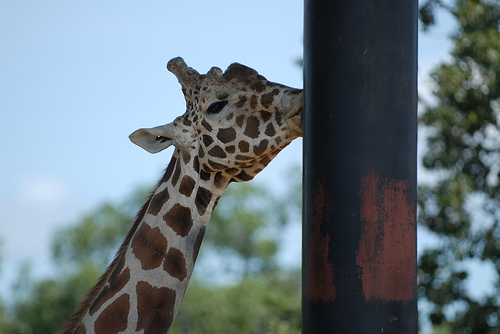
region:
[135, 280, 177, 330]
a brown spot in a giraffe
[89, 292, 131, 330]
a brown spot in a giraffe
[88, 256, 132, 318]
a brown spot in a giraffe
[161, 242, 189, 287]
a brown spot in a giraffe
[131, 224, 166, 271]
a brown spot in a giraffe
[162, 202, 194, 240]
a brown spot in a giraffe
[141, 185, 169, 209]
a brown spot in a giraffe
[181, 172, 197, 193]
a brown spot in a giraffe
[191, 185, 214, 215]
a brown spot in a giraffe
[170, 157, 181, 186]
a brown spot in a giraffe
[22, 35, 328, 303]
a giraffe's head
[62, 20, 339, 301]
a giraffe during the day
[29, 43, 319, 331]
a giraffe licking a pole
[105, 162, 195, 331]
a giraffe's long neck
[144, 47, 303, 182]
a giraffes head during the day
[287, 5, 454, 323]
a tall pole next to the giraffe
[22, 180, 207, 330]
trees in the background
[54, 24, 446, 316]
a giraffe during the day licking a pole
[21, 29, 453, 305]
a giraffe stand up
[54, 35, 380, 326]
a giraffe with his head up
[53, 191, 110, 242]
a tree in a distance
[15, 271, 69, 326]
a tree in a distance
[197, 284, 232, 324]
a tree in a distance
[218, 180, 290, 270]
a tree in a distance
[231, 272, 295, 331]
a tree in a distance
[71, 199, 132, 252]
a tree in a distance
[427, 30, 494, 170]
a tree in a distance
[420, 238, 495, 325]
a tree in a distance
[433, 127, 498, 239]
a tree in a distance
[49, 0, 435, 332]
Giraffe kissing a pole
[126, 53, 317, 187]
A giraffe head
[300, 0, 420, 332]
A black pole with faded red paint on it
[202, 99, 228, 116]
A giraffe's eye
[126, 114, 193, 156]
Down-turned giraffe's ear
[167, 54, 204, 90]
A giraffe's horn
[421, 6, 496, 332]
A blurred, green tree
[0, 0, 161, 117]
A clear, blue sky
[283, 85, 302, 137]
A giraffe's lips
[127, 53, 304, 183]
The head of a giraffe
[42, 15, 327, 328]
a brown and white giraffe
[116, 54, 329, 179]
a giraffe kissing a pole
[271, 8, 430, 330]
a black and brown metal pole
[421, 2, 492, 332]
a leafy green tree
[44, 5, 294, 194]
clear sunny blue sky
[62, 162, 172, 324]
brown hair on the back of a giraffe's neck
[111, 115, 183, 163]
a giraffe's ear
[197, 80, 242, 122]
a black giraffe eye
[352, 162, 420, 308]
brown paint on a black pole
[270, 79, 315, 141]
a giraffe's mouth on a pole